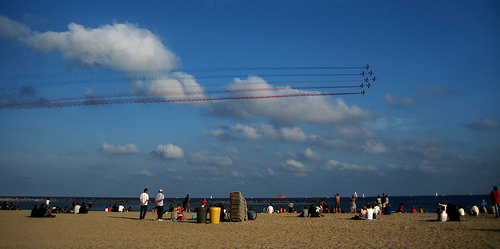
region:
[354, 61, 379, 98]
Eight jets flying in the sky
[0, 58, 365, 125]
Colorful smoke from the jets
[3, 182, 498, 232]
Spectators watching the jets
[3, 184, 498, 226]
People on the beach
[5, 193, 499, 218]
Blue water in the background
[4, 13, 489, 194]
Fluffy white clouds in the sky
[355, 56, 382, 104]
A group of airplanes flying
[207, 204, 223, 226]
A yellow trash can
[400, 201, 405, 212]
A person in a red shirt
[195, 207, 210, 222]
A brown trash can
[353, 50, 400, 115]
The jets are seen in the sky.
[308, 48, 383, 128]
smoke is coming from jet.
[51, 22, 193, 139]
clouds are white in color.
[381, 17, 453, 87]
sky is blue in color.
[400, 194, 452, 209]
water is blue in color.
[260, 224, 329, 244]
the sand is brown in color.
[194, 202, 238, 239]
the dustbin is yellow and grey.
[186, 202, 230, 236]
the dustbin is kept in the sand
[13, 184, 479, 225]
This is a beach scene.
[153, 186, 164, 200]
the cap is white in color.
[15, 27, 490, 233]
People on a beach watching jet fighters.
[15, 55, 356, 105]
Trails of colored smoke left by the jets.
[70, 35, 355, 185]
The sky is cloudy.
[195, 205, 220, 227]
Two garbage cans.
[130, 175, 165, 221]
Two men standing on the beach.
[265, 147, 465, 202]
Sailboats in the distance.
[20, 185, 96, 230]
A group of people seated on the beach.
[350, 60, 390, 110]
Fighter jets in formation.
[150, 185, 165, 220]
The man is wearing a hat.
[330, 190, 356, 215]
Two men in board shorts.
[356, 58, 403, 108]
The jets are flying in the sky.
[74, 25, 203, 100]
The clouds are white in color.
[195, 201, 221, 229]
The dust bin is yellow and grey.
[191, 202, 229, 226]
The dustbin is kept in the sand.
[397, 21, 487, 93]
The sky is blue in color.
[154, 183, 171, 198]
The cap is white in color.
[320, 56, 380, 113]
Smoke comes from the jet.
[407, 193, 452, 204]
The water is blue in color.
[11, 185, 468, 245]
The is the beach scene.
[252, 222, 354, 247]
The sand is brown in color.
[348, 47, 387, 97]
Jet`s racing on the sky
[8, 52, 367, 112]
Smoke being produced by flying jets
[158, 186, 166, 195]
A white cap on the man standing head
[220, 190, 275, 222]
chairs are pilled together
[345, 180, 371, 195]
Hatches are on water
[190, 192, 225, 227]
A yellow and a black bucket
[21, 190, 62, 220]
A man and a woman in black shirts.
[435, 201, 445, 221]
Woman on white shirt sited on sand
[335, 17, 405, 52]
Blue sky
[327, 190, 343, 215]
A man with no shirt.